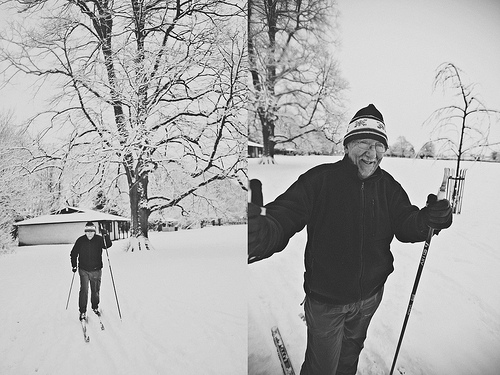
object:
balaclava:
[83, 221, 97, 232]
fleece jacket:
[245, 152, 454, 304]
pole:
[387, 177, 455, 375]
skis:
[100, 237, 123, 320]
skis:
[64, 265, 76, 309]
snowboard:
[80, 317, 93, 342]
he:
[247, 103, 454, 374]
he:
[70, 221, 114, 325]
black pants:
[76, 268, 101, 313]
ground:
[354, 157, 499, 374]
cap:
[344, 103, 390, 149]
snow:
[103, 142, 123, 152]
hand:
[418, 193, 456, 229]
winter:
[0, 0, 499, 375]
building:
[13, 206, 131, 247]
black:
[246, 150, 452, 306]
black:
[69, 236, 114, 272]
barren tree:
[0, 0, 249, 244]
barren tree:
[247, 0, 341, 165]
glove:
[421, 194, 453, 231]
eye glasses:
[347, 137, 390, 154]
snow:
[121, 254, 211, 361]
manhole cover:
[156, 254, 226, 349]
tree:
[4, 1, 244, 248]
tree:
[423, 59, 499, 216]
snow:
[247, 154, 497, 374]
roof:
[13, 207, 130, 227]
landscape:
[1, 0, 499, 375]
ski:
[268, 319, 298, 375]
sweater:
[262, 152, 428, 305]